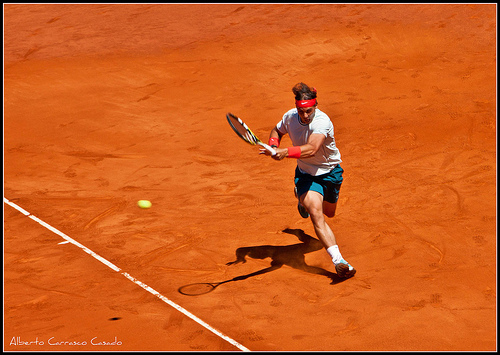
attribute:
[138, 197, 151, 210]
ball — green, yellow, in the air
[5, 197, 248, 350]
line — white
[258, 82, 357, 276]
player — male, playing, running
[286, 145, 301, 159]
wrist band — red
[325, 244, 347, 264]
sock — white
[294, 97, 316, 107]
sweat band — red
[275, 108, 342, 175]
t-shirt — white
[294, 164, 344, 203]
shorts — blue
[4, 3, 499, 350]
court — red